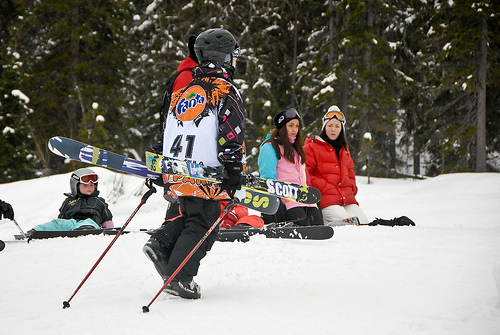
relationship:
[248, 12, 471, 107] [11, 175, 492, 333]
trees covered with snow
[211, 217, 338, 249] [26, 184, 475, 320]
ski in snow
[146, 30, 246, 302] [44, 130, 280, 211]
child carrying skis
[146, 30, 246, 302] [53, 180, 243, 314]
child carrying poles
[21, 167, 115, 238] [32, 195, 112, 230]
boy on ski outfit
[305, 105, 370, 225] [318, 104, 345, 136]
child on hat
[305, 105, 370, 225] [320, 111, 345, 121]
child on goggles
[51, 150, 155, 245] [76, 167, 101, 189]
boy in goggles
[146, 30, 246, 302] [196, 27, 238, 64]
child in helmet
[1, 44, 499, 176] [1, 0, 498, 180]
branches in trees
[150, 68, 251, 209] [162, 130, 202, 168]
jacket with number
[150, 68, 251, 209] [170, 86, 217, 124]
jacket with logos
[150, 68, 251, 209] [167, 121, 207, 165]
jacket has number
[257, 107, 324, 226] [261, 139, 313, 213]
child wearing jacket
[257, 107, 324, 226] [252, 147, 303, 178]
child wearing jacket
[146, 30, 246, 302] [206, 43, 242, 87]
child wearing goggles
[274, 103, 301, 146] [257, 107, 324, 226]
head of child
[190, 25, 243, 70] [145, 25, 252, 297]
head of person